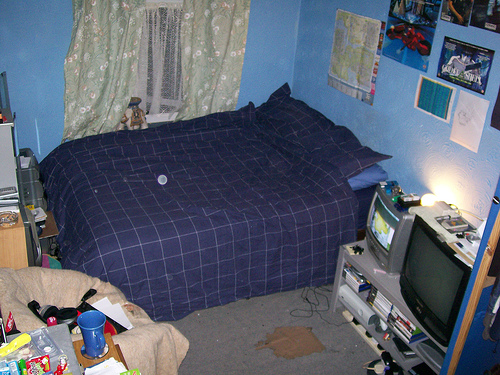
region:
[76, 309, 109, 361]
Blue coffee mug on the end table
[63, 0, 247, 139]
Curtains on the window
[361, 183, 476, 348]
Two televisions on the shelf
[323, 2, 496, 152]
Posters and papers on the wall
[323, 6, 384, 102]
Map on the wall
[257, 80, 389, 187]
Two pillows on the bed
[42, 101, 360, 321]
Blue bedspread on the bed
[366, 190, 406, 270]
Small gray tv on shelf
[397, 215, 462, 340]
Black tv on shelf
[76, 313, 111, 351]
Blue coffee cup on table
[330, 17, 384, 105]
Map attached to a wall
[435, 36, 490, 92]
Poster attached to a wall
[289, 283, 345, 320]
Wires on tan carpet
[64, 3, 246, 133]
Curtains hanging on window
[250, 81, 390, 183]
Pillows in dark blue cases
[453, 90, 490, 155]
White paper on the wall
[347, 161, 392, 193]
Light blue pillow on bed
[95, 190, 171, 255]
the bed is blue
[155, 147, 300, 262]
the bed is checkered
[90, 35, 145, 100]
these are patterned curtains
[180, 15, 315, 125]
curtains are light green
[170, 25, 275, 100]
curtains are light white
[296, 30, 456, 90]
posters on the wall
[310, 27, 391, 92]
this is a map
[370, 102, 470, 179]
the wall is light blue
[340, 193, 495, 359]
these are electronics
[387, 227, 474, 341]
the tv is black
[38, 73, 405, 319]
bedspread matches the pillow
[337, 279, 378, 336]
Xbox game system is in stand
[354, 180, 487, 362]
2 TVs on the stand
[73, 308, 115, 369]
Mug in the table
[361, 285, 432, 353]
games stacked under the TV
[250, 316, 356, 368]
Large stain on the floor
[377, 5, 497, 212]
Several posters on the wall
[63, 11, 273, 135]
curtains on the window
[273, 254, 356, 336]
Wire draped onto the floor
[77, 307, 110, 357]
the cup is blue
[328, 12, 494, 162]
pictures on the wall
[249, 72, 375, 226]
blue pillows on the bed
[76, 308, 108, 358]
light blue mug on a CD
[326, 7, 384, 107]
map on the wall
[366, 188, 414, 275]
small grey TV that is turned on